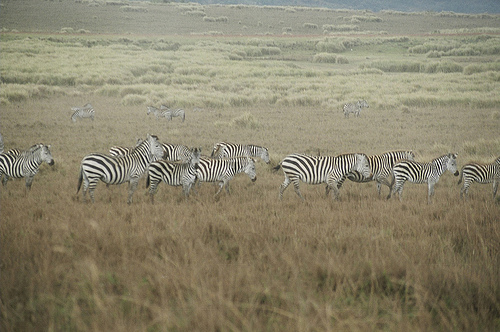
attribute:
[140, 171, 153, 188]
tufts — stiff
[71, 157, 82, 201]
tufts — stiff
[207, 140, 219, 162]
tufts — stiff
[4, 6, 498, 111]
bushes — green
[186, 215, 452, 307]
grass — tall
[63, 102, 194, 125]
zebras — small group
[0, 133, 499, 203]
zebras — large group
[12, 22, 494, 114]
thickets — green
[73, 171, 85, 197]
tail — black, drooping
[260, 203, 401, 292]
grass — brown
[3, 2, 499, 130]
vegetation — tall, green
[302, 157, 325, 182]
stripes — black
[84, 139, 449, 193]
herd — large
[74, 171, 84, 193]
hair — black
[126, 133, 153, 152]
mane — small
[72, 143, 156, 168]
back — zebra's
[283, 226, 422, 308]
grass — tall